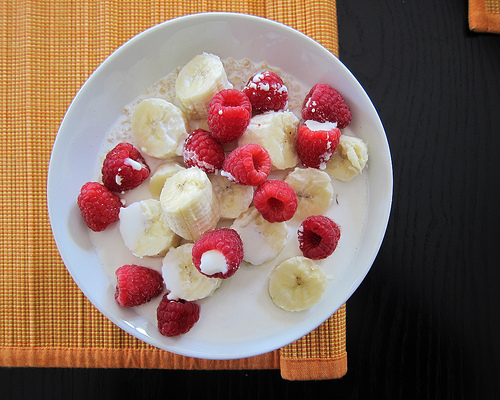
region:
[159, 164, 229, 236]
The banana is sliced.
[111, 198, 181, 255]
The banana is sliced.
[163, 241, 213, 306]
The banana is sliced.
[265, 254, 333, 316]
The banana is sliced.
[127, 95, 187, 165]
The banana is sliced.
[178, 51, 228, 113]
The banana is sliced.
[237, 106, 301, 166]
The banana is sliced.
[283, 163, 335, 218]
The banana is sliced.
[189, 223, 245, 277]
The raspberry is red.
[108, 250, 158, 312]
The raspberry is red.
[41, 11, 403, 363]
a bowl of fruit in milk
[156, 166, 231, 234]
a chunk of banana in milk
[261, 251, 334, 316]
a chunk of banana in milk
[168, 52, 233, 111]
a chunk of banana in milk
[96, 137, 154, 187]
a raspberry in milk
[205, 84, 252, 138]
a raspberry in milk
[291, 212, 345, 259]
a raspberry in milk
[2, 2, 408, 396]
a bowl of fruit on a table mat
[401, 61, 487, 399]
a section of wooden tabl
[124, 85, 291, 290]
a group of fruit in milk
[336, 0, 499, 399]
shiny black painted table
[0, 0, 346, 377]
woven orange fabric placemat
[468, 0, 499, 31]
woven orange fabric placemat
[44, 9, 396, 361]
bowl of cereal with milk, raspberries, and bananas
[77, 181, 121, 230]
juicy red raspberry in milk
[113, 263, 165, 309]
juicy red raspberry in milk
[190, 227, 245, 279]
juicy red raspberry in milk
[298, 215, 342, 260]
juicy red raspberry in milk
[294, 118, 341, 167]
juicy red raspberry in milk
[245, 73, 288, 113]
juicy red raspberry in milk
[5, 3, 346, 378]
an orange placemat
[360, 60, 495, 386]
a black table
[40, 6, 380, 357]
a white bowl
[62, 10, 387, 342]
a bowl of fruit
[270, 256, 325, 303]
a slice of banana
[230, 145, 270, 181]
a red raspberry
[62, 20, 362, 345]
a bowl of milk with pieces of banana and raspberry in it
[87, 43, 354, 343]
milk with fruit in it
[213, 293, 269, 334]
the white milk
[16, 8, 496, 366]
a bowl of fruit on a placemat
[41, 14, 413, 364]
the color of the plate is white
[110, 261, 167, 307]
there are red berries on the plate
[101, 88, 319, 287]
a mix of slice bananas and berries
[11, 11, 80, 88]
A brown place mat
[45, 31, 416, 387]
A platted of dessert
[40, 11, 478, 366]
fruits placed on a black table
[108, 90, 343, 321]
fruits combined with milk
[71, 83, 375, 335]
there are thirteen red berries